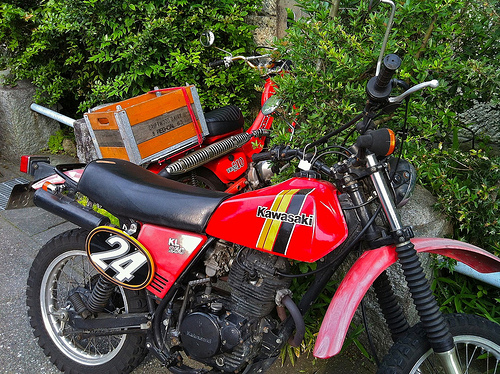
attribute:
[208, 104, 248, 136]
seat — black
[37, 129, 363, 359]
motorcycle — red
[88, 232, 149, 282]
number — white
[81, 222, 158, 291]
logo — black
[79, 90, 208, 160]
crate — orange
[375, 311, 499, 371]
wheel — black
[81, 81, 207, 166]
crate — orange, wooden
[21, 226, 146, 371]
wheel — black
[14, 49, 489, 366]
motorcycle — red, black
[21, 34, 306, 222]
scooter — red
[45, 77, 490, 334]
motorcycle — red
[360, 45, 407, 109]
rubber — black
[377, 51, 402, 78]
handle — black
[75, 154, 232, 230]
seat — black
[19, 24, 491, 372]
motorcycle — red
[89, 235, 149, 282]
24 — number